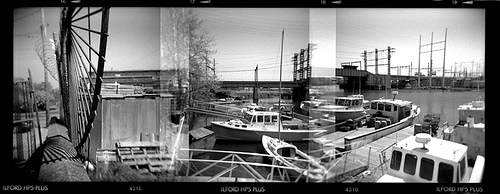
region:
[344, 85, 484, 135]
Body of water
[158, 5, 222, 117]
Large tree in the middle of the ships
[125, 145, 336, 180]
Bridge leading to the dock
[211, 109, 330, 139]
Ship in the water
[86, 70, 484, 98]
Strip of land with a cross-bridge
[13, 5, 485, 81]
Clear sky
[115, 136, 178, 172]
Wooden blocks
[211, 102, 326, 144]
boat anchored in a marina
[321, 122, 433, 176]
wooden dock in a marina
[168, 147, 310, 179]
walk way next to the marina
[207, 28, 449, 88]
electricity wires and poles next to the marina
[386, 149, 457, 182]
dark windows on a boat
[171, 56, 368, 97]
draw bridge over the marina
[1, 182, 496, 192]
white text on the bottom of the image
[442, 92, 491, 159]
boat parked in the marina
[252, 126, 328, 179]
small boat parked next to a dock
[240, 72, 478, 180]
various boats in a dock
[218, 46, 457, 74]
power lines in background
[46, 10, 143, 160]
large spoked wheel on left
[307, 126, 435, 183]
wooden plank pier by boats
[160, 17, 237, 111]
tree in middle of pier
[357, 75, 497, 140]
water off the pier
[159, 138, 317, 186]
metal pole fencing in front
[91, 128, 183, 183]
wooden pallets leaning against building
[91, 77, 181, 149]
wooden shack near pier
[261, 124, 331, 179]
small fishing boat near fencing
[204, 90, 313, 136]
this is a ship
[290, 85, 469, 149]
this is a ship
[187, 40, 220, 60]
a branch without leaves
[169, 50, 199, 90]
a branch without leaves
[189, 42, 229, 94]
a branch without leaves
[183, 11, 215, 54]
a branch without leaves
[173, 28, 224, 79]
a branch without leaves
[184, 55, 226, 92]
a branch without leaves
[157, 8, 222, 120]
tree in the middle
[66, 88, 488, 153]
body of water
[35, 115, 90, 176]
part of a concrete rail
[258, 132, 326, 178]
small boat facing the opposite direction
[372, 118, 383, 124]
boxes in a boat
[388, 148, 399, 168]
window on a boat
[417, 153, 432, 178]
window on a boat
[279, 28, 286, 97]
tall power pole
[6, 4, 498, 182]
a scene at the harbor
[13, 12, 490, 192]
a black and white photo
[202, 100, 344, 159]
a ship on water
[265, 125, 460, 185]
a wooden dock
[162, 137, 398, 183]
a metal guardrail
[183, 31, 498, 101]
a bridge background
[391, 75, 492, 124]
a body of water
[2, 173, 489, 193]
a watermark on the bottom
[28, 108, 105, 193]
a thick concrete rail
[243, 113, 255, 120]
glass window on boat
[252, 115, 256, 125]
glass window on boat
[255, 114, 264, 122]
glass window on boat